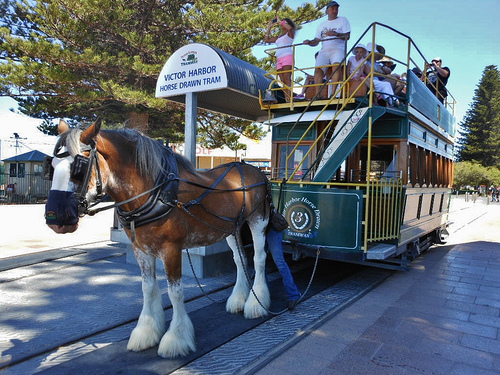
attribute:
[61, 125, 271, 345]
horse — clydesdale, brown, white, harnessed, large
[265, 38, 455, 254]
trolley — green, yellow, waiting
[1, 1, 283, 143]
tree — green, large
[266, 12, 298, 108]
woman — standing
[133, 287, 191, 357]
hooves — hair, large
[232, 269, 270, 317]
hooves — hair, large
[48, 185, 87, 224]
mask — black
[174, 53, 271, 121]
shelter — blue, white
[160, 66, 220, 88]
letters — blue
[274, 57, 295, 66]
shorts — pink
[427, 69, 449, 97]
shirt — black